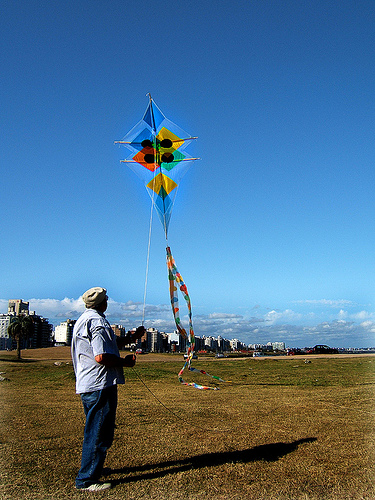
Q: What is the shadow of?
A: The man.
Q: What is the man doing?
A: Flying a kite.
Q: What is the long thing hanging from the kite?
A: The tail.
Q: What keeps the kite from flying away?
A: The string.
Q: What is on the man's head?
A: A hat.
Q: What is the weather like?
A: Partly cloudy.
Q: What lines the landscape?
A: Buildings.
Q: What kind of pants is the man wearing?
A: Blue jeans.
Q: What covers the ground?
A: Brown grass.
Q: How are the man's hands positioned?
A: In fists.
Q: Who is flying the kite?
A: An older man.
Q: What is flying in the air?
A: A kite.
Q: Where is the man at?
A: In an empty field outside of the city.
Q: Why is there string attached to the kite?
A: So that the kite can be held on to.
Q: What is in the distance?
A: The city line.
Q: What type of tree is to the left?
A: A palm tree.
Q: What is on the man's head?
A: A hat.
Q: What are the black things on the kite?
A: Circles that are apart of the design.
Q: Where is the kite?
A: In the air.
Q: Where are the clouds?
A: In the sky.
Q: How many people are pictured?
A: One.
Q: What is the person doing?
A: Flying a kite.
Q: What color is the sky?
A: Blue.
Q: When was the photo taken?
A: Daytime.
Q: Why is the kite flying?
A: There is wind.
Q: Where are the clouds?
A: In the sky.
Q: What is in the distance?
A: Buildings.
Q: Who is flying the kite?
A: The man.